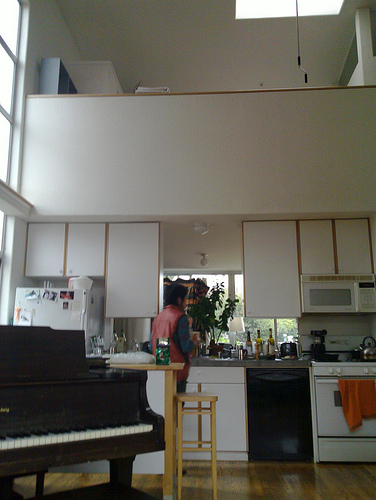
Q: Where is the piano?
A: In kitchen.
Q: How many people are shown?
A: One.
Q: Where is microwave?
A: Above stove.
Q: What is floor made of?
A: Wood.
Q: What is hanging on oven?
A: Towel.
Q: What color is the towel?
A: Orange.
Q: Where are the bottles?
A: Countertop.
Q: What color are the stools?
A: Tan.